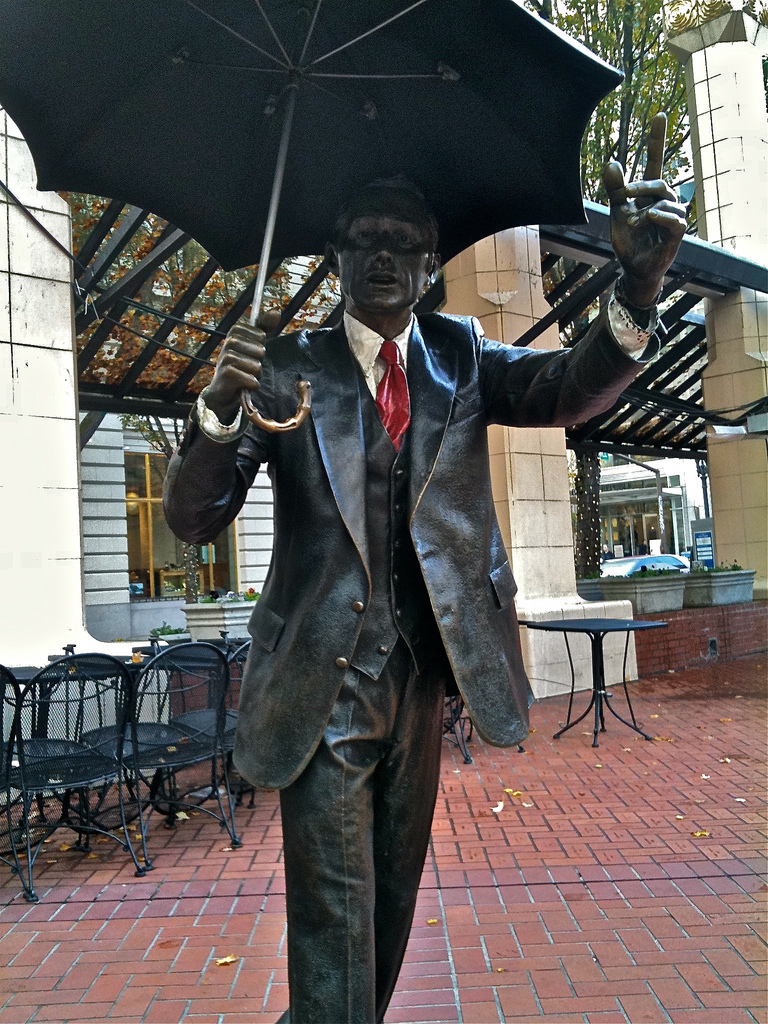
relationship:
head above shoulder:
[322, 168, 440, 316] [270, 302, 490, 388]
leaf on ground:
[212, 950, 239, 969] [417, 761, 757, 1022]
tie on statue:
[378, 338, 408, 433] [170, 110, 688, 1018]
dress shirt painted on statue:
[337, 309, 423, 443] [170, 110, 688, 1018]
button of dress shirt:
[332, 654, 348, 666] [161, 296, 654, 1021]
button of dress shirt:
[352, 600, 364, 612] [161, 296, 654, 1021]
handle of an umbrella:
[240, 83, 312, 435] [3, 0, 623, 436]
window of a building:
[125, 447, 235, 597] [2, 4, 463, 734]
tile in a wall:
[1, 143, 67, 212] [4, 114, 89, 672]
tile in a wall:
[3, 205, 72, 279] [4, 114, 89, 672]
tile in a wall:
[6, 276, 70, 346] [4, 114, 89, 672]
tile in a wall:
[1, 350, 97, 411] [1, 110, 97, 666]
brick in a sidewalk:
[493, 865, 524, 885] [5, 664, 765, 1015]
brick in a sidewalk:
[183, 875, 214, 896] [5, 664, 765, 1015]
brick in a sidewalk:
[82, 903, 121, 923] [5, 664, 765, 1015]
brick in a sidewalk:
[644, 797, 672, 809] [5, 664, 765, 1015]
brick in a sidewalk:
[40, 881, 86, 906] [5, 664, 765, 1015]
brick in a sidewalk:
[572, 977, 649, 998] [5, 664, 765, 1015]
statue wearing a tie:
[2, 96, 671, 1019] [376, 327, 410, 441]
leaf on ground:
[215, 953, 240, 968] [9, 637, 763, 1018]